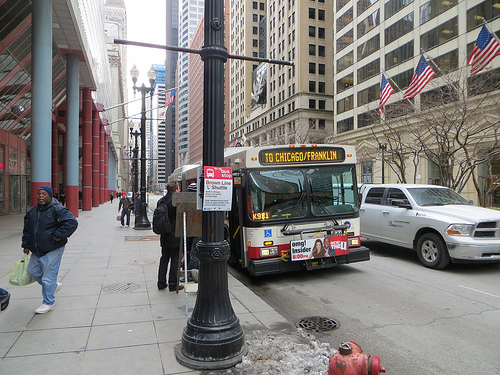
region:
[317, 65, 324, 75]
window on the building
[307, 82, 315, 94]
window on the building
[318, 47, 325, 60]
window on the building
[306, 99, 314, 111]
window on the building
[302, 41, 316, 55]
window on the building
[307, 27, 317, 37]
window on the building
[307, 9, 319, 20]
window on the building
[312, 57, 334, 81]
window on the building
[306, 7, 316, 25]
window on the building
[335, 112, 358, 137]
side window on wall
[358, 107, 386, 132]
side window on wall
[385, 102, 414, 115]
side window on wall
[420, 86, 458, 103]
side window on wall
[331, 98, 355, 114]
side window on wall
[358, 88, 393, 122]
side window on wall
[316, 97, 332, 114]
side window on wall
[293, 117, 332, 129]
side window on wall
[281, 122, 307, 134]
side window on wall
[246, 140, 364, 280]
bus on a street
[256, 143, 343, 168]
sign on a bus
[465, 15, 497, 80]
flag on a bulding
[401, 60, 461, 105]
flag on a bulding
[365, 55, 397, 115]
flag on a building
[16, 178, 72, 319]
man on a side walk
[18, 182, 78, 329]
man holding a bag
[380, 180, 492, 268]
truck on a street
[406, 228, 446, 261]
tire on a truck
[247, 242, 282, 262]
light on a bus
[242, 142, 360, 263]
front end of a bus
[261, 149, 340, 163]
sign says " to Chicago/franklin"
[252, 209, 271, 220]
bus number "K981"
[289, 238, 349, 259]
banner on bus advertise tv show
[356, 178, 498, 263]
white truck to left of bus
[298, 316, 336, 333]
manhole drain on ground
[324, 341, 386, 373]
part of fire hydrant; foreground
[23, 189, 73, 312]
male wearing jacket and jeans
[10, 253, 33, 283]
male is carrying bag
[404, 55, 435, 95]
one of three flags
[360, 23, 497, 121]
three american flags on building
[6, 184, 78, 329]
heavy set man wearing a stocking cap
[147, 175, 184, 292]
man in backpack waiting to board bus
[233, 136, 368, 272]
front of a city bus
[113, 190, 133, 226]
man in red stocking cap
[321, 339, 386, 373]
red fire hydrant on curb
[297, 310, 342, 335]
man hole cover in street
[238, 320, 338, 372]
dirty snow on the sidewalk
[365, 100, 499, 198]
row of leafless trees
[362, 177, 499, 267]
white truck on the street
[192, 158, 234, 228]
red and white sign on post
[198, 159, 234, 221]
sign on post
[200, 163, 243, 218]
sign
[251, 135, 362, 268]
red and white passenger bus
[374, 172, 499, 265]
white car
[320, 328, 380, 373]
red fire hydrant on side walk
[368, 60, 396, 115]
red white and blue flag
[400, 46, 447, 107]
red white and blue flag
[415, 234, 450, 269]
A tire on a vehicle.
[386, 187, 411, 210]
A window on a vehicle.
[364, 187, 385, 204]
A window on a vehicle.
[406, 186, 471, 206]
A window on a vehicle.